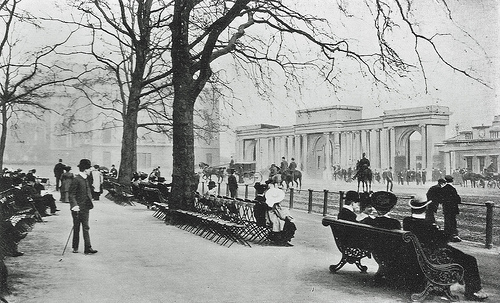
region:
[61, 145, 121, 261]
man walking along sidewalk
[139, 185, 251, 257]
row of metal chairs covered in snow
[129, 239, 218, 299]
ground covered in black and white snow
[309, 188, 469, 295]
row of people sitting on metal bench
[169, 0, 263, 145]
large tree with no leaves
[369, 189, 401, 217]
large black hat on lady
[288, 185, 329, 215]
black and white guard fencing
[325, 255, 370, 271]
black metal leg on bench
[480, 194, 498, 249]
black metal fencing post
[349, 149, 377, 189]
person on horseback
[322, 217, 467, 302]
ornate metal park bench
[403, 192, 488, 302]
man wearing a hat sitting on park bench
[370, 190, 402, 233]
woman wearing a hat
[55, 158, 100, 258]
man is walking near tree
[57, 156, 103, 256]
man holding a cane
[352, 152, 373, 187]
person riding a horse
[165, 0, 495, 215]
tall tree next to chairs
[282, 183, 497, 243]
stone steps behind fence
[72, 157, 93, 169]
hat is black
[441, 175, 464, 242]
person next to fence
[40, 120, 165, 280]
man holding cane on sidewalk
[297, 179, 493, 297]
three people sitting on bench looking at street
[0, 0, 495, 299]
many townspeople gathered in town square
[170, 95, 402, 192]
men on horses in street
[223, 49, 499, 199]
large, pillared entrance on street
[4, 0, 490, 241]
no leaves on trees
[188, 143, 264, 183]
man on horse drawn carriage on street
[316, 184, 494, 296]
three people wearing hats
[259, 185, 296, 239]
woman wearing large white hat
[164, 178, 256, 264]
empty chairs on sidewalk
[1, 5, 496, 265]
Old timey picture of people in city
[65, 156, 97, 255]
man in a black bowler hat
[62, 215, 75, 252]
a black walking cane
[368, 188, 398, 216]
fancy black hat on woman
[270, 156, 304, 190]
men are riding horses in street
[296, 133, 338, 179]
columns on building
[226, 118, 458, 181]
the building is white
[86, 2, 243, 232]
trees lining the street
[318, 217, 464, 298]
an ornate park bench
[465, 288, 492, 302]
man's black dress shoe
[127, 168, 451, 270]
people sitting on the bench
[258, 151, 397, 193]
men riding the horse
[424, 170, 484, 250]
people by the railings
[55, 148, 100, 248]
a man s looking out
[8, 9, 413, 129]
the trees are bare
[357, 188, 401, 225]
women wearing big hats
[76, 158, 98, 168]
a man wearing a fedora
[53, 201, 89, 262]
a man carrying a cane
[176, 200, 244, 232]
the chairs are empty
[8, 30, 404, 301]
the picture is old